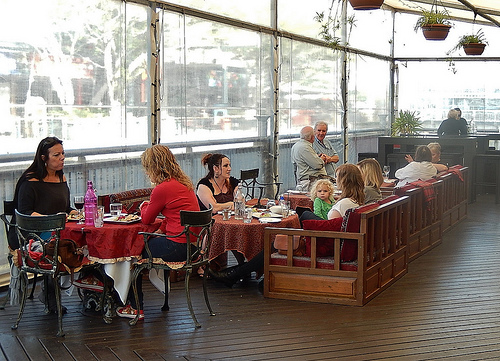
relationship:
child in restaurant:
[305, 178, 337, 214] [0, 2, 496, 356]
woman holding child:
[277, 156, 364, 241] [305, 172, 337, 213]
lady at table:
[68, 143, 204, 320] [405, 121, 486, 168]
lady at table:
[7, 137, 79, 314] [405, 121, 486, 168]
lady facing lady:
[68, 143, 204, 320] [7, 137, 79, 314]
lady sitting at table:
[68, 143, 204, 320] [53, 201, 162, 327]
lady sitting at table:
[7, 137, 79, 314] [53, 201, 162, 327]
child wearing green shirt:
[310, 178, 337, 220] [313, 195, 337, 219]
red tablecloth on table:
[61, 217, 161, 260] [53, 201, 162, 327]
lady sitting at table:
[68, 143, 204, 320] [54, 214, 156, 314]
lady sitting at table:
[7, 137, 79, 314] [54, 214, 156, 314]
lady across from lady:
[68, 143, 204, 320] [7, 137, 79, 314]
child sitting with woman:
[310, 178, 337, 220] [299, 162, 364, 219]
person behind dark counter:
[453, 108, 471, 137] [376, 130, 474, 202]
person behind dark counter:
[435, 108, 466, 141] [376, 130, 474, 202]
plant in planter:
[313, 0, 359, 52] [348, 0, 385, 9]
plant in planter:
[398, 0, 456, 32] [421, 23, 452, 40]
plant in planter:
[445, 26, 489, 73] [462, 43, 485, 54]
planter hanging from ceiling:
[348, 0, 385, 9] [381, 0, 498, 27]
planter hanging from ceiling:
[421, 23, 452, 40] [381, 0, 498, 27]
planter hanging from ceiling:
[462, 43, 485, 54] [381, 0, 498, 27]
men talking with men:
[291, 120, 341, 191] [291, 120, 341, 191]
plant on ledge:
[388, 105, 420, 135] [390, 126, 498, 136]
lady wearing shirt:
[68, 143, 204, 320] [132, 174, 206, 239]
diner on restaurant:
[192, 151, 242, 220] [0, 2, 496, 356]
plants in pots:
[231, 27, 318, 124] [337, 3, 498, 77]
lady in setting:
[7, 137, 79, 314] [43, 65, 317, 295]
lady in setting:
[68, 143, 204, 320] [43, 65, 317, 295]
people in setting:
[7, 120, 448, 322] [43, 65, 317, 295]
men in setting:
[291, 120, 341, 191] [43, 65, 317, 295]